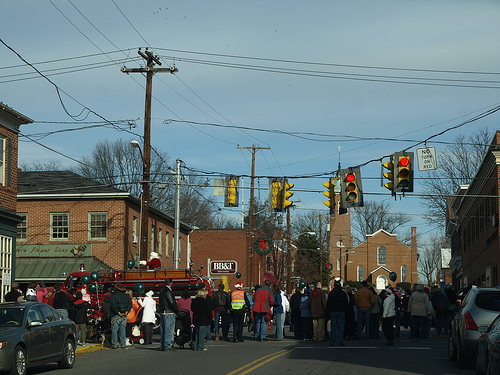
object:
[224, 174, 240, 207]
lights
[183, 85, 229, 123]
wires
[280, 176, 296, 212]
lights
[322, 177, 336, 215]
lights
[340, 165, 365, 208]
lights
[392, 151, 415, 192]
lights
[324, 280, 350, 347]
people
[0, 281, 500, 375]
street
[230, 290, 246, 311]
vest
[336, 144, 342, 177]
spire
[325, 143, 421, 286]
church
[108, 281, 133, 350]
man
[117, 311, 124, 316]
hands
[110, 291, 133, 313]
back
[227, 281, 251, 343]
man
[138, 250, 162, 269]
santa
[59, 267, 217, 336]
firetruck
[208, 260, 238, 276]
sign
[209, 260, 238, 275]
bank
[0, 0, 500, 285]
sky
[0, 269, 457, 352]
parade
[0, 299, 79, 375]
car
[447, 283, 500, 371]
car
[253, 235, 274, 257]
wreath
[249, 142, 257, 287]
pole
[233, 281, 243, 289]
hat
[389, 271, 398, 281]
balloon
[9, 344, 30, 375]
wheel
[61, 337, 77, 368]
wheel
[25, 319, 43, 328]
mirror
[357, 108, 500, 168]
cable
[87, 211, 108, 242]
window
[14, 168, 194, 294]
building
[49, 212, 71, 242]
window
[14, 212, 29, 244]
window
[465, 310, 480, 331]
light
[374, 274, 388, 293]
door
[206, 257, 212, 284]
post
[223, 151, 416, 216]
group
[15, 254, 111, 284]
awning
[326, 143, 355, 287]
steeple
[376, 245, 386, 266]
windows